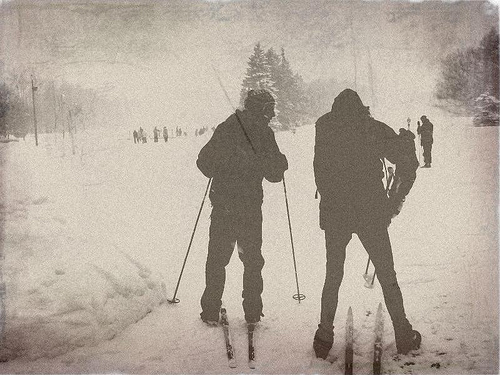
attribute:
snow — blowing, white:
[410, 246, 497, 374]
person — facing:
[309, 83, 434, 358]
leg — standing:
[309, 232, 356, 344]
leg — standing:
[362, 228, 414, 343]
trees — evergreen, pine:
[235, 40, 319, 131]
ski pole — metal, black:
[159, 176, 214, 313]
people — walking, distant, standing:
[129, 126, 209, 146]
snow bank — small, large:
[3, 164, 172, 364]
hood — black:
[329, 88, 365, 118]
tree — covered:
[472, 28, 499, 128]